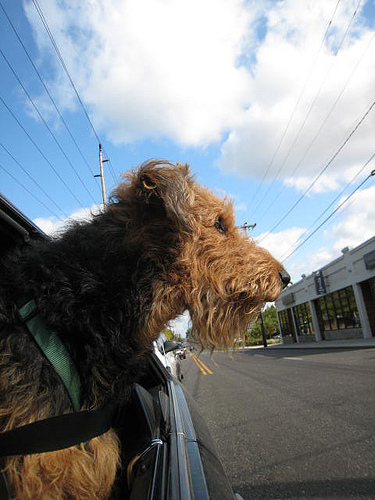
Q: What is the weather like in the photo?
A: It is cloudy.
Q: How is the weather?
A: It is cloudy.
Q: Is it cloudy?
A: Yes, it is cloudy.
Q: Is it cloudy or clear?
A: It is cloudy.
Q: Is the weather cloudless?
A: No, it is cloudy.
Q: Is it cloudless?
A: No, it is cloudy.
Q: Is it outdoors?
A: Yes, it is outdoors.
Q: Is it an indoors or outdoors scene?
A: It is outdoors.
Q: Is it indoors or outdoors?
A: It is outdoors.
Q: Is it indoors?
A: No, it is outdoors.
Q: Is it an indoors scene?
A: No, it is outdoors.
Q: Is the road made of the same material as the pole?
A: No, the road is made of cement and the pole is made of wood.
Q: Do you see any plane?
A: No, there are no airplanes.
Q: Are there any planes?
A: No, there are no planes.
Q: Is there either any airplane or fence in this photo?
A: No, there are no airplanes or fences.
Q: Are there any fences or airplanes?
A: No, there are no airplanes or fences.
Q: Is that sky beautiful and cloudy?
A: Yes, the sky is beautiful and cloudy.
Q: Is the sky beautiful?
A: Yes, the sky is beautiful.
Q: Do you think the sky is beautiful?
A: Yes, the sky is beautiful.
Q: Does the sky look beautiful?
A: Yes, the sky is beautiful.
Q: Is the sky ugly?
A: No, the sky is beautiful.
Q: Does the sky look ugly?
A: No, the sky is beautiful.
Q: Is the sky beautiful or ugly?
A: The sky is beautiful.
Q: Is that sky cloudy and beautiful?
A: Yes, the sky is cloudy and beautiful.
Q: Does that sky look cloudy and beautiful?
A: Yes, the sky is cloudy and beautiful.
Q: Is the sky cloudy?
A: Yes, the sky is cloudy.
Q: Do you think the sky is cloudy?
A: Yes, the sky is cloudy.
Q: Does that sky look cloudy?
A: Yes, the sky is cloudy.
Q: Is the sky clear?
A: No, the sky is cloudy.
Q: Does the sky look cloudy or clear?
A: The sky is cloudy.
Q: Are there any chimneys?
A: No, there are no chimneys.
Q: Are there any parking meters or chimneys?
A: No, there are no chimneys or parking meters.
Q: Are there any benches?
A: No, there are no benches.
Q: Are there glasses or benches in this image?
A: No, there are no benches or glasses.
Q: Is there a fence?
A: No, there are no fences.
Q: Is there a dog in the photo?
A: Yes, there is a dog.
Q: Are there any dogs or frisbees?
A: Yes, there is a dog.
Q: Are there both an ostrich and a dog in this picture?
A: No, there is a dog but no ostriches.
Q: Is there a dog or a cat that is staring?
A: Yes, the dog is staring.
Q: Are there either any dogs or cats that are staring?
A: Yes, the dog is staring.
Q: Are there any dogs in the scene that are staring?
A: Yes, there is a dog that is staring.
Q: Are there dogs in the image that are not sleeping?
A: Yes, there is a dog that is staring.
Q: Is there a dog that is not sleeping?
A: Yes, there is a dog that is staring.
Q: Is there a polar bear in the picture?
A: No, there are no polar bears.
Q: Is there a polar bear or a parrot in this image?
A: No, there are no polar bears or parrots.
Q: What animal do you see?
A: The animal is a dog.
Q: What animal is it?
A: The animal is a dog.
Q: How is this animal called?
A: This is a dog.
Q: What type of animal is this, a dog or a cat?
A: This is a dog.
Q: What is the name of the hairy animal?
A: The animal is a dog.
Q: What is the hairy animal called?
A: The animal is a dog.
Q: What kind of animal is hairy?
A: The animal is a dog.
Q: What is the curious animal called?
A: The animal is a dog.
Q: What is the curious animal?
A: The animal is a dog.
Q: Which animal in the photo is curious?
A: The animal is a dog.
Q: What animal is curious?
A: The animal is a dog.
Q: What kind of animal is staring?
A: The animal is a dog.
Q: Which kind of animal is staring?
A: The animal is a dog.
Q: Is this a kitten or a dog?
A: This is a dog.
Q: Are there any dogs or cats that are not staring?
A: No, there is a dog but it is staring.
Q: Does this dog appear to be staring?
A: Yes, the dog is staring.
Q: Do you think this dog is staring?
A: Yes, the dog is staring.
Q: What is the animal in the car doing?
A: The dog is staring.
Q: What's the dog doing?
A: The dog is staring.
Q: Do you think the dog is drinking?
A: No, the dog is staring.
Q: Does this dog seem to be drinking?
A: No, the dog is staring.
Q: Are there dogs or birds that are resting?
A: No, there is a dog but it is staring.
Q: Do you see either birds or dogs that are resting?
A: No, there is a dog but it is staring.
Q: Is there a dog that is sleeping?
A: No, there is a dog but it is staring.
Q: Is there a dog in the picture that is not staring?
A: No, there is a dog but it is staring.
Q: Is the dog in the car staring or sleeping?
A: The dog is staring.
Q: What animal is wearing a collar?
A: The dog is wearing a collar.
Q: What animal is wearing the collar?
A: The dog is wearing a collar.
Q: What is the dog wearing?
A: The dog is wearing a collar.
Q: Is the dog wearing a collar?
A: Yes, the dog is wearing a collar.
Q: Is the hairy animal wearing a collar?
A: Yes, the dog is wearing a collar.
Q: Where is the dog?
A: The dog is in the car.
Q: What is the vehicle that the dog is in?
A: The vehicle is a car.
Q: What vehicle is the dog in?
A: The dog is in the car.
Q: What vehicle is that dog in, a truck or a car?
A: The dog is in a car.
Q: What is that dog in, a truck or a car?
A: The dog is in a car.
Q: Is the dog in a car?
A: Yes, the dog is in a car.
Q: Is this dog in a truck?
A: No, the dog is in a car.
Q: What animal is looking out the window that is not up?
A: The animal is a dog.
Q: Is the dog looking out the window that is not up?
A: Yes, the dog is looking out the window.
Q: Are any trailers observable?
A: No, there are no trailers.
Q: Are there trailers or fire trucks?
A: No, there are no trailers or fire trucks.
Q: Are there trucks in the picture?
A: No, there are no trucks.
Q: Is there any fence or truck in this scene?
A: No, there are no trucks or fences.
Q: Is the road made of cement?
A: Yes, the road is made of cement.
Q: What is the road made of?
A: The road is made of concrete.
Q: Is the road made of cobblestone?
A: No, the road is made of cement.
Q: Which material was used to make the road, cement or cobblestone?
A: The road is made of cement.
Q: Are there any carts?
A: No, there are no carts.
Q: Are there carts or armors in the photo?
A: No, there are no carts or armors.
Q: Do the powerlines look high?
A: Yes, the powerlines are high.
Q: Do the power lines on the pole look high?
A: Yes, the power lines are high.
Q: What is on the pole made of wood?
A: The powerlines are on the pole.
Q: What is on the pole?
A: The powerlines are on the pole.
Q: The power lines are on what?
A: The power lines are on the pole.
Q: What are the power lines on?
A: The power lines are on the pole.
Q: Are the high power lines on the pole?
A: Yes, the wires are on the pole.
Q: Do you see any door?
A: Yes, there is a door.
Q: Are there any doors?
A: Yes, there is a door.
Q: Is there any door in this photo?
A: Yes, there is a door.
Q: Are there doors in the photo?
A: Yes, there is a door.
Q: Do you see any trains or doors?
A: Yes, there is a door.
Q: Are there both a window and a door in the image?
A: Yes, there are both a door and a window.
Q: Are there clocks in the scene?
A: No, there are no clocks.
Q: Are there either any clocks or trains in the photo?
A: No, there are no clocks or trains.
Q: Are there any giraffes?
A: No, there are no giraffes.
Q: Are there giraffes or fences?
A: No, there are no giraffes or fences.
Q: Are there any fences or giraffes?
A: No, there are no giraffes or fences.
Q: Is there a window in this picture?
A: Yes, there is a window.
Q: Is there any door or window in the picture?
A: Yes, there is a window.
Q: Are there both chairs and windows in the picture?
A: No, there is a window but no chairs.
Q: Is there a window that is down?
A: Yes, there is a window that is down.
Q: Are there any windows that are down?
A: Yes, there is a window that is down.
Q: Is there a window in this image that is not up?
A: Yes, there is a window that is down.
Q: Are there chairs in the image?
A: No, there are no chairs.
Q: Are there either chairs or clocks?
A: No, there are no chairs or clocks.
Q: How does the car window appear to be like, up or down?
A: The window is down.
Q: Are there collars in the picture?
A: Yes, there is a collar.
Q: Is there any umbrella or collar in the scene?
A: Yes, there is a collar.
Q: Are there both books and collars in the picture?
A: No, there is a collar but no books.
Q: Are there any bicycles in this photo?
A: No, there are no bicycles.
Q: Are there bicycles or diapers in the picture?
A: No, there are no bicycles or diapers.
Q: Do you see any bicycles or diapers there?
A: No, there are no bicycles or diapers.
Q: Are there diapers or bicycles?
A: No, there are no bicycles or diapers.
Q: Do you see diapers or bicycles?
A: No, there are no bicycles or diapers.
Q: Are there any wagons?
A: No, there are no wagons.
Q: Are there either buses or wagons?
A: No, there are no wagons or buses.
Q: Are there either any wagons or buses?
A: No, there are no wagons or buses.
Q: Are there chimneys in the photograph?
A: No, there are no chimneys.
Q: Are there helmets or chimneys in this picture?
A: No, there are no chimneys or helmets.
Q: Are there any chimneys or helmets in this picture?
A: No, there are no chimneys or helmets.